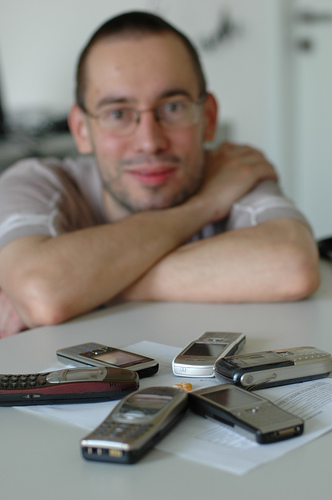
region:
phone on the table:
[210, 390, 286, 446]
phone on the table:
[93, 409, 173, 457]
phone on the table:
[0, 362, 110, 406]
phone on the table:
[79, 338, 148, 374]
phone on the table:
[178, 333, 227, 382]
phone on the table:
[240, 345, 325, 381]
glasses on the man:
[90, 100, 197, 138]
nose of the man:
[123, 131, 169, 157]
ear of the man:
[197, 88, 216, 142]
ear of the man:
[53, 105, 90, 152]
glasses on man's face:
[72, 86, 213, 148]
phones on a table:
[31, 317, 327, 463]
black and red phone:
[4, 364, 125, 410]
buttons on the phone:
[4, 366, 48, 390]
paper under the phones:
[187, 436, 230, 477]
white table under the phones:
[31, 436, 67, 476]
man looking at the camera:
[53, 24, 253, 217]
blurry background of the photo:
[230, 14, 291, 73]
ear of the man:
[198, 85, 237, 142]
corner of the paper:
[219, 451, 265, 496]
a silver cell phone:
[55, 337, 158, 378]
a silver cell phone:
[171, 330, 243, 379]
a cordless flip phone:
[215, 343, 330, 387]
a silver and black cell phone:
[190, 378, 303, 443]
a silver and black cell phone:
[77, 384, 186, 463]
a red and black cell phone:
[0, 367, 139, 406]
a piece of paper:
[12, 338, 330, 472]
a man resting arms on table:
[0, 8, 322, 327]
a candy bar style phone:
[171, 329, 245, 378]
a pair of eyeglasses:
[77, 91, 216, 136]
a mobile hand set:
[165, 314, 252, 378]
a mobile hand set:
[219, 340, 325, 394]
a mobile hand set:
[196, 370, 311, 465]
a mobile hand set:
[74, 377, 203, 479]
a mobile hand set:
[46, 327, 175, 380]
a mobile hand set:
[0, 357, 149, 404]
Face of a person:
[90, 45, 205, 207]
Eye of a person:
[156, 83, 205, 135]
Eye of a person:
[102, 88, 148, 145]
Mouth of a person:
[117, 155, 188, 192]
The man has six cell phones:
[8, 215, 326, 486]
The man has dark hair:
[22, 4, 235, 95]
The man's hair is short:
[75, 9, 231, 99]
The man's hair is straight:
[51, 5, 233, 108]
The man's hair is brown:
[69, 12, 224, 112]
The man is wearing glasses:
[69, 81, 219, 135]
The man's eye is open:
[98, 95, 135, 137]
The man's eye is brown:
[101, 103, 134, 131]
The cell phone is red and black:
[7, 362, 138, 398]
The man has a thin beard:
[86, 143, 231, 214]